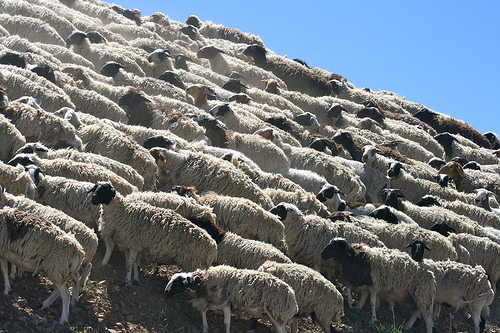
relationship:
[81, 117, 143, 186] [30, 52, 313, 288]
sheep next to sheep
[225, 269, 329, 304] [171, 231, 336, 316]
wool on sheep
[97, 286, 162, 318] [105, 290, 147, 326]
dirt on ground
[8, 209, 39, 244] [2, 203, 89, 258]
spot on back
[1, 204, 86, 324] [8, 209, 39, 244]
sheep with spot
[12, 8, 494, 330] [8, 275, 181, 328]
sheep walking up hill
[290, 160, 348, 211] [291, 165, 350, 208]
sheep with face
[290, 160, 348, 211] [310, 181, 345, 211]
sheep with spots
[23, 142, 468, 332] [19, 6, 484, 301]
hill covered with sheep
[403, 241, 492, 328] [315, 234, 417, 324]
sheep next to sheep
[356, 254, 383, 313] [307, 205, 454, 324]
leg on sheep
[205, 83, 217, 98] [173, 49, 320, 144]
ear on sheep